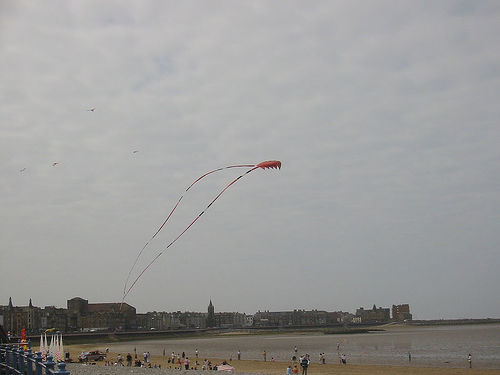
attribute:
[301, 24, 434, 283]
clouds — white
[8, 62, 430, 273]
sky — blue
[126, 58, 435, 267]
clouds — white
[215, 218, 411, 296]
clouds — white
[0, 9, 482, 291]
sky — blue, bue, hazy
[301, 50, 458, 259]
clouds — white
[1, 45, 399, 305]
clouds — white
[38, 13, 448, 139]
clouds — white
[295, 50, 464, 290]
clouds — white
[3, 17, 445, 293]
sky — blue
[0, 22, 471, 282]
clouds — white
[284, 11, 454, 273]
clouds — white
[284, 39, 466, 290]
clouds — white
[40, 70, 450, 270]
clouds — white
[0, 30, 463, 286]
sky — blue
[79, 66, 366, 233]
clouds — white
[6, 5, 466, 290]
clouds — white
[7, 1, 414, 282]
clouds — white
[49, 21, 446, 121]
clouds — white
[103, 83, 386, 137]
clouds — wispy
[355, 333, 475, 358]
waters — calm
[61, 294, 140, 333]
building — tall, brown, apartment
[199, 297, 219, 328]
tower — grey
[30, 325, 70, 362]
fountain — big, white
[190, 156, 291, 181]
kite — big, orange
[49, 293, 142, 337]
building — large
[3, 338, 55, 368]
railing — cement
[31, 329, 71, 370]
decorations — tall, white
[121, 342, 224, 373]
crowd — people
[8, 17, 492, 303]
sky — blue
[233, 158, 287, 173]
kite — red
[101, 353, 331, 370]
people — standing on a beach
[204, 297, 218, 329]
tall building — near the sea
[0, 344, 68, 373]
poled railing — near the beach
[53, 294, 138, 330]
brown building — large, near sea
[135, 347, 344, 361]
water — on the edge of a beach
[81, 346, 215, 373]
sand — on the beach